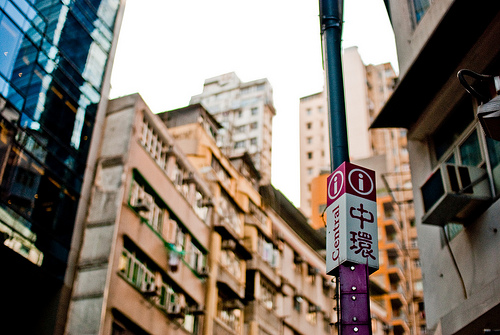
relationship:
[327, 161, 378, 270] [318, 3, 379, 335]
sign on pole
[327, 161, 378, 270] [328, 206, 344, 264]
sign says central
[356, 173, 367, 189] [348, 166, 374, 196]
i inside circle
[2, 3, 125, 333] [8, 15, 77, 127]
building with windows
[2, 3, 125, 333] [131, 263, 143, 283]
building has window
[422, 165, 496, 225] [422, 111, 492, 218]
air conditioning in window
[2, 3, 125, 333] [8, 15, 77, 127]
building has windows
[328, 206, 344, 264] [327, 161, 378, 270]
central on sign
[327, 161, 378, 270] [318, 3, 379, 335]
sign in pole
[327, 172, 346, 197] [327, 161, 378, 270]
symbol on sign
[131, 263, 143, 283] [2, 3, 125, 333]
window on building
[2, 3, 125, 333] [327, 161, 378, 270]
building next to sign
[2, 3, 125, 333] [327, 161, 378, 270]
building across from sign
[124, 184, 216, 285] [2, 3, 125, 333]
strip on building